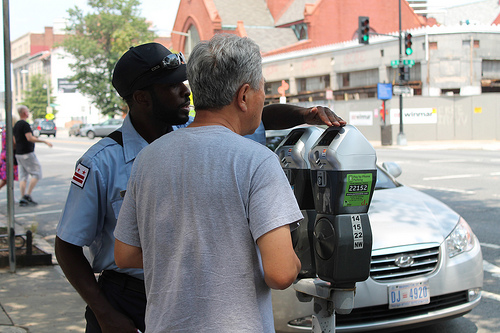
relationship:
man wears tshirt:
[115, 34, 302, 332] [114, 124, 299, 332]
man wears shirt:
[13, 107, 52, 209] [13, 119, 36, 154]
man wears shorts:
[13, 107, 52, 209] [16, 156, 44, 177]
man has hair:
[115, 34, 302, 332] [186, 32, 263, 108]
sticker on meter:
[342, 173, 373, 212] [276, 125, 373, 290]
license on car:
[388, 280, 430, 308] [267, 128, 483, 331]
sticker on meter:
[349, 216, 366, 250] [276, 125, 373, 290]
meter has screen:
[276, 125, 373, 290] [320, 131, 337, 146]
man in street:
[13, 107, 52, 209] [6, 136, 495, 332]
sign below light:
[390, 58, 413, 69] [405, 45, 411, 54]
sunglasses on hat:
[138, 52, 188, 73] [112, 38, 191, 90]